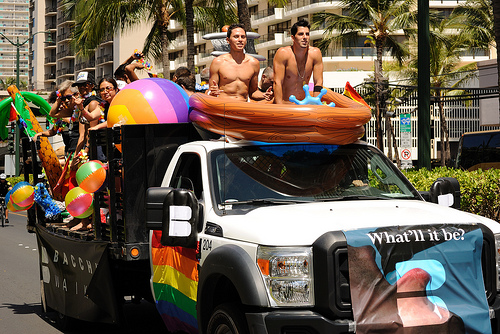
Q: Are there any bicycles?
A: No, there are no bicycles.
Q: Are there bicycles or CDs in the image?
A: No, there are no bicycles or cds.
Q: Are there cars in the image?
A: No, there are no cars.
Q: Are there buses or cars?
A: No, there are no cars or buses.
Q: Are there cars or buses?
A: No, there are no cars or buses.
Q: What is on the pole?
A: The sign is on the pole.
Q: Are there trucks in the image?
A: Yes, there is a truck.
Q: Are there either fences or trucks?
A: Yes, there is a truck.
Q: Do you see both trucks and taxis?
A: No, there is a truck but no taxis.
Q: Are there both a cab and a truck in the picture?
A: No, there is a truck but no taxis.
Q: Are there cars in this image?
A: No, there are no cars.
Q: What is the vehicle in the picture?
A: The vehicle is a truck.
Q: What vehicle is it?
A: The vehicle is a truck.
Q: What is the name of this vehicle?
A: This is a truck.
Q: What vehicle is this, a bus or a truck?
A: This is a truck.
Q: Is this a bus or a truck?
A: This is a truck.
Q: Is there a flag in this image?
A: Yes, there is a flag.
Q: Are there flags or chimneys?
A: Yes, there is a flag.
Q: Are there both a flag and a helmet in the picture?
A: No, there is a flag but no helmets.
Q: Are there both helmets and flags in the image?
A: No, there is a flag but no helmets.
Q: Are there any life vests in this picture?
A: No, there are no life vests.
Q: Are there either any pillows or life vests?
A: No, there are no life vests or pillows.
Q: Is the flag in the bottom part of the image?
A: Yes, the flag is in the bottom of the image.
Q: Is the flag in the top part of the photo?
A: No, the flag is in the bottom of the image.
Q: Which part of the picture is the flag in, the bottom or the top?
A: The flag is in the bottom of the image.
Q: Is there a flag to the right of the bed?
A: Yes, there is a flag to the right of the bed.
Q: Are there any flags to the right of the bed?
A: Yes, there is a flag to the right of the bed.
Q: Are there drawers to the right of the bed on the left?
A: No, there is a flag to the right of the bed.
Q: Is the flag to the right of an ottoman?
A: No, the flag is to the right of the bed.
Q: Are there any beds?
A: Yes, there is a bed.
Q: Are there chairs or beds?
A: Yes, there is a bed.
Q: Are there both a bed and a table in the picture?
A: No, there is a bed but no tables.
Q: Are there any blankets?
A: No, there are no blankets.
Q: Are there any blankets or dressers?
A: No, there are no blankets or dressers.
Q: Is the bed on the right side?
A: No, the bed is on the left of the image.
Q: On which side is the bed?
A: The bed is on the left of the image.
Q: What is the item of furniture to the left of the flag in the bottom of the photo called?
A: The piece of furniture is a bed.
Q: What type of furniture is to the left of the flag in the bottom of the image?
A: The piece of furniture is a bed.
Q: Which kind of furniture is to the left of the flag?
A: The piece of furniture is a bed.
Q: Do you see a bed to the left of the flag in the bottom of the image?
A: Yes, there is a bed to the left of the flag.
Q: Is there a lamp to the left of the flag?
A: No, there is a bed to the left of the flag.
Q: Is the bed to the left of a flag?
A: Yes, the bed is to the left of a flag.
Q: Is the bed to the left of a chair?
A: No, the bed is to the left of a flag.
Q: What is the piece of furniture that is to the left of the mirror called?
A: The piece of furniture is a bed.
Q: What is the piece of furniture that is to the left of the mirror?
A: The piece of furniture is a bed.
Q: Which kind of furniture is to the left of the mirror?
A: The piece of furniture is a bed.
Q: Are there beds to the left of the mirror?
A: Yes, there is a bed to the left of the mirror.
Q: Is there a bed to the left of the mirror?
A: Yes, there is a bed to the left of the mirror.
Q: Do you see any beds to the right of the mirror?
A: No, the bed is to the left of the mirror.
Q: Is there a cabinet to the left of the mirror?
A: No, there is a bed to the left of the mirror.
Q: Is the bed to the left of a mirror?
A: Yes, the bed is to the left of a mirror.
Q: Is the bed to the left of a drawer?
A: No, the bed is to the left of a mirror.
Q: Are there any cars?
A: No, there are no cars.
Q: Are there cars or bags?
A: No, there are no cars or bags.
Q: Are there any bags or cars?
A: No, there are no cars or bags.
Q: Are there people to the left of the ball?
A: Yes, there are people to the left of the ball.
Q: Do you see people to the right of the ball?
A: No, the people are to the left of the ball.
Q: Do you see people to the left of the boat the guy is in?
A: Yes, there are people to the left of the boat.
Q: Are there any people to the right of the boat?
A: No, the people are to the left of the boat.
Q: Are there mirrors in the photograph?
A: Yes, there is a mirror.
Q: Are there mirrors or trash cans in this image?
A: Yes, there is a mirror.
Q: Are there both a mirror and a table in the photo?
A: No, there is a mirror but no tables.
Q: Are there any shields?
A: No, there are no shields.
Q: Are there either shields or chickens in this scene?
A: No, there are no shields or chickens.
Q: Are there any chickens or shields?
A: No, there are no shields or chickens.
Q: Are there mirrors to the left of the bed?
A: No, the mirror is to the right of the bed.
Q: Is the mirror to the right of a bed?
A: Yes, the mirror is to the right of a bed.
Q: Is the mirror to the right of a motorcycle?
A: No, the mirror is to the right of a bed.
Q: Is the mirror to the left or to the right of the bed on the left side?
A: The mirror is to the right of the bed.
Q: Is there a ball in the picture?
A: Yes, there is a ball.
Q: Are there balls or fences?
A: Yes, there is a ball.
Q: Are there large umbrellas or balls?
A: Yes, there is a large ball.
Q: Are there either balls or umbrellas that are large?
A: Yes, the ball is large.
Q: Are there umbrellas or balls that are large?
A: Yes, the ball is large.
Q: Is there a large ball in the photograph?
A: Yes, there is a large ball.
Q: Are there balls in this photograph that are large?
A: Yes, there is a ball that is large.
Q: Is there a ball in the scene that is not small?
A: Yes, there is a large ball.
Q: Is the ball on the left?
A: Yes, the ball is on the left of the image.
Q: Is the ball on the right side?
A: No, the ball is on the left of the image.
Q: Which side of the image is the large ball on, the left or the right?
A: The ball is on the left of the image.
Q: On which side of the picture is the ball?
A: The ball is on the left of the image.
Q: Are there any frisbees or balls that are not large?
A: No, there is a ball but it is large.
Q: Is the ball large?
A: Yes, the ball is large.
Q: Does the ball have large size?
A: Yes, the ball is large.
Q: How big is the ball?
A: The ball is large.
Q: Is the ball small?
A: No, the ball is large.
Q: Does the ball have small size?
A: No, the ball is large.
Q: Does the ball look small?
A: No, the ball is large.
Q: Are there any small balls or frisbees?
A: No, there is a ball but it is large.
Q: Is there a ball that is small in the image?
A: No, there is a ball but it is large.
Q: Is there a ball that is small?
A: No, there is a ball but it is large.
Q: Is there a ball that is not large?
A: No, there is a ball but it is large.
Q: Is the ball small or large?
A: The ball is large.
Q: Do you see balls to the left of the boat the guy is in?
A: Yes, there is a ball to the left of the boat.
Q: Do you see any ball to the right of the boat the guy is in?
A: No, the ball is to the left of the boat.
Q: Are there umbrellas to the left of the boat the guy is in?
A: No, there is a ball to the left of the boat.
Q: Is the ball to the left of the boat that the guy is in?
A: Yes, the ball is to the left of the boat.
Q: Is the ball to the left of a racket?
A: No, the ball is to the left of the boat.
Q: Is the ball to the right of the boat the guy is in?
A: No, the ball is to the left of the boat.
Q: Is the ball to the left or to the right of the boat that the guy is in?
A: The ball is to the left of the boat.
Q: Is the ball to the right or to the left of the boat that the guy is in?
A: The ball is to the left of the boat.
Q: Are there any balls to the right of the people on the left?
A: Yes, there is a ball to the right of the people.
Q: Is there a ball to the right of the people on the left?
A: Yes, there is a ball to the right of the people.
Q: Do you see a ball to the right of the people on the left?
A: Yes, there is a ball to the right of the people.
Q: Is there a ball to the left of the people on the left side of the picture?
A: No, the ball is to the right of the people.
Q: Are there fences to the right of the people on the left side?
A: No, there is a ball to the right of the people.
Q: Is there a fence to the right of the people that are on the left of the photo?
A: No, there is a ball to the right of the people.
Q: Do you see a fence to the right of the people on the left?
A: No, there is a ball to the right of the people.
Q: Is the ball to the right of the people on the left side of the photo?
A: Yes, the ball is to the right of the people.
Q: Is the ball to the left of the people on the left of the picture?
A: No, the ball is to the right of the people.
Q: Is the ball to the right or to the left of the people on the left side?
A: The ball is to the right of the people.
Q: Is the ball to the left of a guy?
A: Yes, the ball is to the left of a guy.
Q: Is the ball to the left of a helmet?
A: No, the ball is to the left of a guy.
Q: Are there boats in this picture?
A: Yes, there is a boat.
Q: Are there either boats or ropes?
A: Yes, there is a boat.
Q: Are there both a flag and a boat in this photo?
A: Yes, there are both a boat and a flag.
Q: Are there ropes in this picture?
A: No, there are no ropes.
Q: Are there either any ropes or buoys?
A: No, there are no ropes or buoys.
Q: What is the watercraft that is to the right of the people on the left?
A: The watercraft is a boat.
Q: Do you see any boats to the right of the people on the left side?
A: Yes, there is a boat to the right of the people.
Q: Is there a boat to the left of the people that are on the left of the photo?
A: No, the boat is to the right of the people.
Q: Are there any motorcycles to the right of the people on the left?
A: No, there is a boat to the right of the people.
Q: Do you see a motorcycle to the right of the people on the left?
A: No, there is a boat to the right of the people.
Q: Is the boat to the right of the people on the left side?
A: Yes, the boat is to the right of the people.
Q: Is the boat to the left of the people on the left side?
A: No, the boat is to the right of the people.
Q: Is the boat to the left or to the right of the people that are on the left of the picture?
A: The boat is to the right of the people.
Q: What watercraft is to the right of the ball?
A: The watercraft is a boat.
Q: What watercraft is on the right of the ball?
A: The watercraft is a boat.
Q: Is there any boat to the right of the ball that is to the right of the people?
A: Yes, there is a boat to the right of the ball.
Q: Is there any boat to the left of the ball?
A: No, the boat is to the right of the ball.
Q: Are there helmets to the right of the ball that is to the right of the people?
A: No, there is a boat to the right of the ball.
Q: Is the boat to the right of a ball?
A: Yes, the boat is to the right of a ball.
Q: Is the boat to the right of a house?
A: No, the boat is to the right of a ball.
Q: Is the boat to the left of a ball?
A: No, the boat is to the right of a ball.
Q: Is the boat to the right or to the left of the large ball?
A: The boat is to the right of the ball.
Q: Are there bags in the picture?
A: No, there are no bags.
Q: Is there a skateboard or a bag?
A: No, there are no bags or skateboards.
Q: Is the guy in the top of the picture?
A: Yes, the guy is in the top of the image.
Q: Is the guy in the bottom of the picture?
A: No, the guy is in the top of the image.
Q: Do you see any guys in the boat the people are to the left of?
A: Yes, there is a guy in the boat.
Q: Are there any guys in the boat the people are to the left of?
A: Yes, there is a guy in the boat.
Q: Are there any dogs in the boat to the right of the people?
A: No, there is a guy in the boat.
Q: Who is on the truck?
A: The guy is on the truck.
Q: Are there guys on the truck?
A: Yes, there is a guy on the truck.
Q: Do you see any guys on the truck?
A: Yes, there is a guy on the truck.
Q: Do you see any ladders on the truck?
A: No, there is a guy on the truck.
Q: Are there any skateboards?
A: No, there are no skateboards.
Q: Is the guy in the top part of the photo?
A: Yes, the guy is in the top of the image.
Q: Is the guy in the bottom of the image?
A: No, the guy is in the top of the image.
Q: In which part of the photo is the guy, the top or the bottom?
A: The guy is in the top of the image.